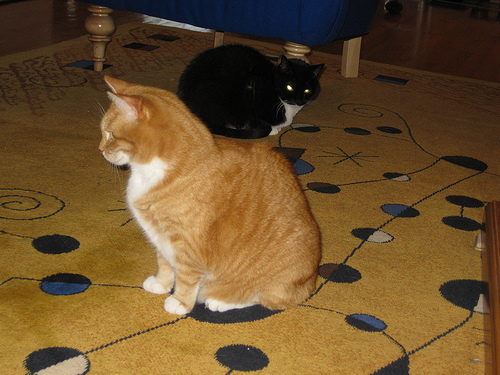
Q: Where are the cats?
A: On the ground.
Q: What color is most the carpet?
A: Yellow.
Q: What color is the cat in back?
A: Black.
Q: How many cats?
A: Two.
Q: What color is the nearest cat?
A: Yellow.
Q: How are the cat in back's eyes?
A: Glowing.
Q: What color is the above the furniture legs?
A: Blue.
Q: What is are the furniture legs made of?
A: Wood.